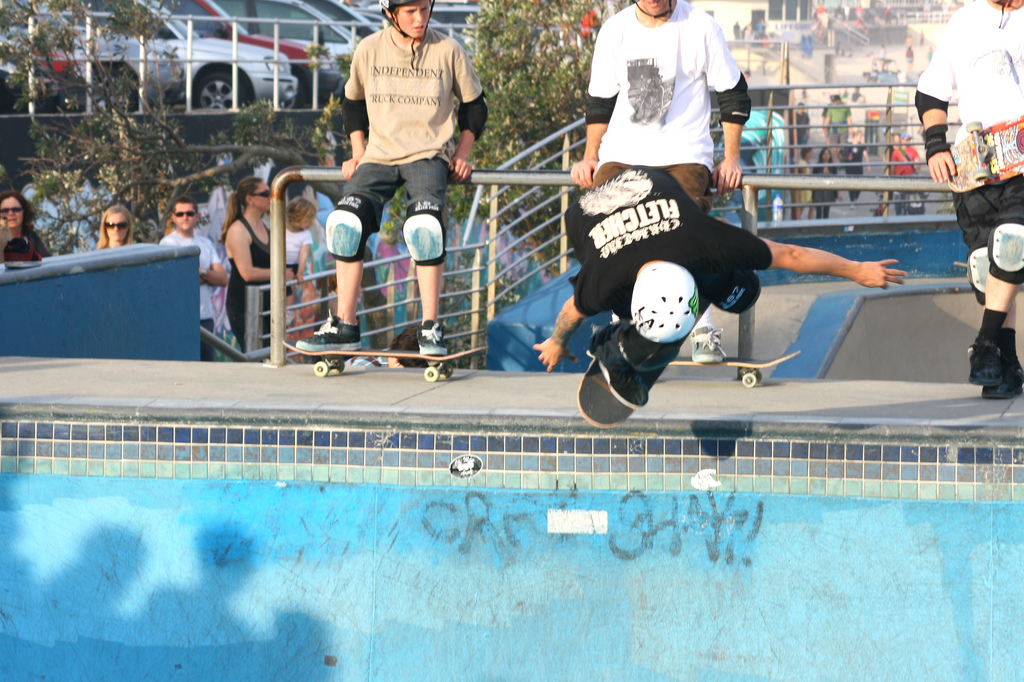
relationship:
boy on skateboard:
[303, 10, 504, 367] [262, 337, 496, 389]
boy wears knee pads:
[303, 10, 504, 367] [315, 203, 452, 273]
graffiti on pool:
[410, 476, 779, 595] [0, 419, 1024, 681]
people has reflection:
[2, 494, 352, 680] [39, 509, 333, 680]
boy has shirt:
[283, 0, 514, 378] [337, 28, 489, 176]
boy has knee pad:
[283, 0, 514, 378] [307, 203, 374, 266]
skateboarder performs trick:
[518, 156, 919, 422] [508, 146, 939, 436]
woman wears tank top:
[210, 160, 273, 349] [214, 213, 281, 294]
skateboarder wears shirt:
[518, 156, 919, 422] [545, 146, 787, 309]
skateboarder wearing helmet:
[518, 156, 919, 422] [611, 254, 704, 356]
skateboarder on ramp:
[519, 155, 909, 400] [4, 457, 1020, 678]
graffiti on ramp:
[410, 476, 779, 595] [4, 457, 1020, 678]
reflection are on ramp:
[0, 487, 344, 680] [4, 457, 1020, 678]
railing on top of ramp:
[246, 148, 1020, 378] [4, 457, 1020, 678]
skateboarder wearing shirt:
[518, 156, 919, 422] [581, 159, 774, 337]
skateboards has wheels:
[279, 338, 494, 382] [309, 351, 459, 388]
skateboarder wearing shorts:
[566, 3, 765, 390] [655, 159, 727, 209]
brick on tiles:
[773, 468, 840, 490] [5, 416, 1018, 682]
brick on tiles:
[944, 440, 1001, 477] [5, 416, 1018, 682]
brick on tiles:
[110, 416, 160, 440] [5, 416, 1018, 682]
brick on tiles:
[242, 440, 288, 479] [5, 416, 1018, 682]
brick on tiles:
[384, 423, 424, 460] [5, 416, 1018, 682]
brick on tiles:
[743, 446, 804, 494] [5, 416, 1018, 682]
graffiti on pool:
[410, 479, 778, 594] [0, 410, 1020, 672]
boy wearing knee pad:
[283, 0, 514, 378] [394, 206, 455, 274]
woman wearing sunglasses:
[74, 179, 152, 268] [93, 211, 139, 240]